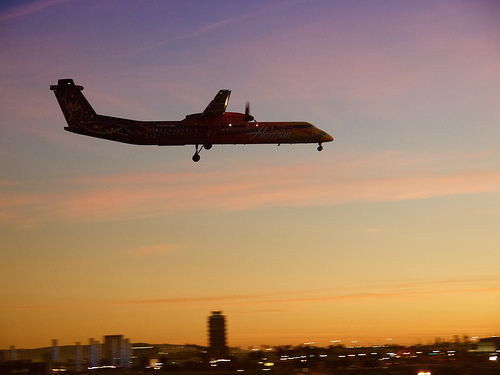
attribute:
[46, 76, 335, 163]
airplane — propellar-driven, flying, solo, landing, descending, colorful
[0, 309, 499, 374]
skyline — city, in background, lit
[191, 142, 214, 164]
landing gear — down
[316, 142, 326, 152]
landing gear — lowered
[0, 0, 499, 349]
sky — purple pink, sunset, yell, hazy, blue pink, purple, orange, yellow, cloudy, blue, pink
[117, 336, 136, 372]
skyscraper — white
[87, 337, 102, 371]
skyscraper — white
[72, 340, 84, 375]
skyscraper — white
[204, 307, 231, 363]
building — in background, very tall, tall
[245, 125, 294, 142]
word — white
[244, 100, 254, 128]
propellar — in motion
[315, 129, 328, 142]
stripe — blue